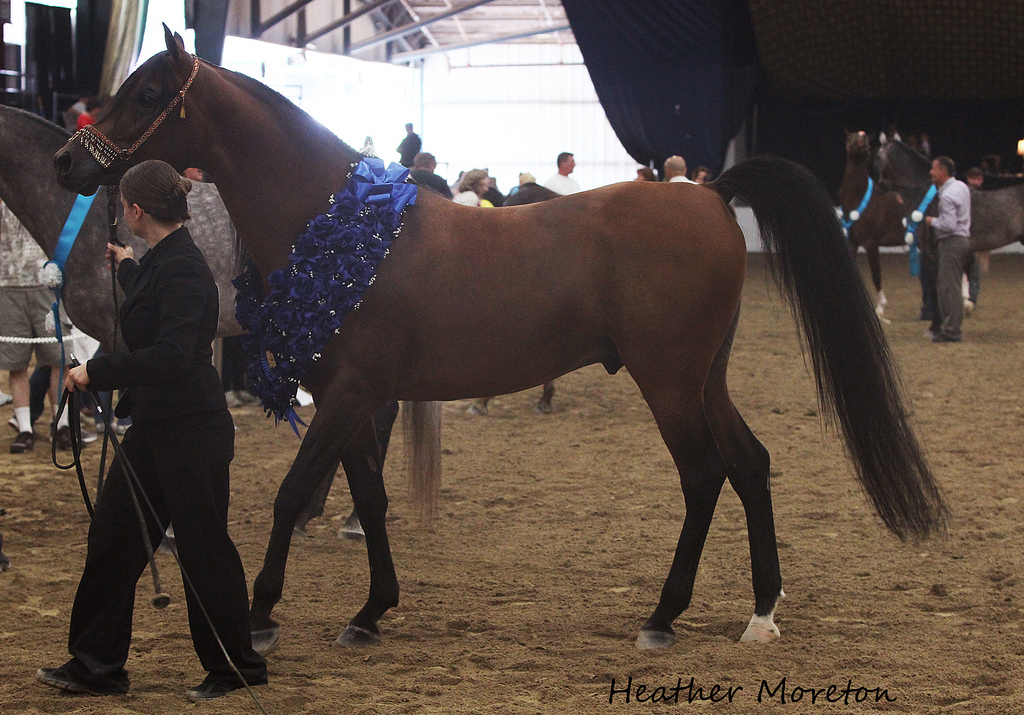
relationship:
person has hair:
[38, 162, 285, 703] [107, 164, 194, 226]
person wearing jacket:
[38, 162, 285, 703] [94, 257, 231, 425]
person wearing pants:
[38, 162, 285, 703] [64, 390, 270, 673]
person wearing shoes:
[38, 162, 285, 703] [35, 640, 274, 698]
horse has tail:
[46, 17, 954, 653] [714, 144, 952, 547]